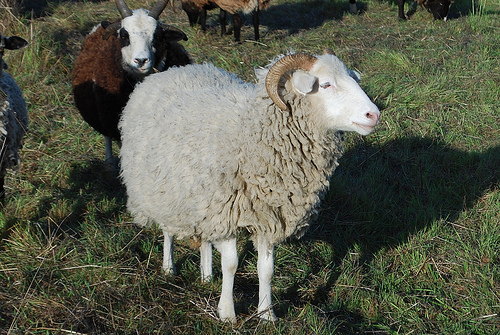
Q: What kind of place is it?
A: It is a pasture.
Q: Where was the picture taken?
A: It was taken at the pasture.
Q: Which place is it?
A: It is a pasture.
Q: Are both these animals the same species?
A: Yes, all the animals are sheep.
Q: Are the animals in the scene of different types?
A: No, all the animals are sheep.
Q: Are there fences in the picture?
A: No, there are no fences.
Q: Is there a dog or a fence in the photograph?
A: No, there are no fences or dogs.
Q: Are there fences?
A: No, there are no fences.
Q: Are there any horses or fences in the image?
A: No, there are no fences or horses.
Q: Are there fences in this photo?
A: No, there are no fences.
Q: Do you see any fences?
A: No, there are no fences.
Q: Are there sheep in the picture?
A: Yes, there is a sheep.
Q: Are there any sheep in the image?
A: Yes, there is a sheep.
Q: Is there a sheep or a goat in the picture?
A: Yes, there is a sheep.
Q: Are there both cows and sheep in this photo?
A: No, there is a sheep but no cows.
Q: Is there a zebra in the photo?
A: No, there are no zebras.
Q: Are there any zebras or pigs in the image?
A: No, there are no zebras or pigs.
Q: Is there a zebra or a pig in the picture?
A: No, there are no zebras or pigs.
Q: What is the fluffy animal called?
A: The animal is a sheep.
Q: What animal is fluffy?
A: The animal is a sheep.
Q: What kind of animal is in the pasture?
A: The animal is a sheep.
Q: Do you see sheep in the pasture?
A: Yes, there is a sheep in the pasture.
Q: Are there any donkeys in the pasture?
A: No, there is a sheep in the pasture.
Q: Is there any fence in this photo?
A: No, there are no fences.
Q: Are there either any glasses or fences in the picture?
A: No, there are no fences or glasses.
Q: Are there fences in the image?
A: No, there are no fences.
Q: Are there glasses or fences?
A: No, there are no fences or glasses.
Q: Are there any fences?
A: No, there are no fences.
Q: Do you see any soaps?
A: No, there are no soaps.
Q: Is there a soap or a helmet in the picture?
A: No, there are no soaps or helmets.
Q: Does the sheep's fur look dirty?
A: Yes, the fur is dirty.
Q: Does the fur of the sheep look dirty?
A: Yes, the fur is dirty.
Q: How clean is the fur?
A: The fur is dirty.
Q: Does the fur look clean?
A: No, the fur is dirty.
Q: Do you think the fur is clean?
A: No, the fur is dirty.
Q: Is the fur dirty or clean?
A: The fur is dirty.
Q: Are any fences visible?
A: No, there are no fences.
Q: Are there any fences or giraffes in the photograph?
A: No, there are no fences or giraffes.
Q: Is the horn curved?
A: Yes, the horn is curved.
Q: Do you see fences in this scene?
A: No, there are no fences.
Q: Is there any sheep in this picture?
A: Yes, there is a sheep.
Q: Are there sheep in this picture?
A: Yes, there is a sheep.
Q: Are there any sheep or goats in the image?
A: Yes, there is a sheep.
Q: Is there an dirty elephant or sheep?
A: Yes, there is a dirty sheep.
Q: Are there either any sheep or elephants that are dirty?
A: Yes, the sheep is dirty.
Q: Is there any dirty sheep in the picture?
A: Yes, there is a dirty sheep.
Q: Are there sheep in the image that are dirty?
A: Yes, there is a sheep that is dirty.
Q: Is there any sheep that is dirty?
A: Yes, there is a sheep that is dirty.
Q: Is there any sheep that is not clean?
A: Yes, there is a dirty sheep.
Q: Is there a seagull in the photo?
A: No, there are no seagulls.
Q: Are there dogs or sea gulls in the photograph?
A: No, there are no sea gulls or dogs.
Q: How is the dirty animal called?
A: The animal is a sheep.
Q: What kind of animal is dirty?
A: The animal is a sheep.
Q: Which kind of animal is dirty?
A: The animal is a sheep.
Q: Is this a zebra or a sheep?
A: This is a sheep.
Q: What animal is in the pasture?
A: The sheep is in the pasture.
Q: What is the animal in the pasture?
A: The animal is a sheep.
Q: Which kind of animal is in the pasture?
A: The animal is a sheep.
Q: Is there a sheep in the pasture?
A: Yes, there is a sheep in the pasture.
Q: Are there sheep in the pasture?
A: Yes, there is a sheep in the pasture.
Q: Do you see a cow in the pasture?
A: No, there is a sheep in the pasture.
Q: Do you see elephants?
A: No, there are no elephants.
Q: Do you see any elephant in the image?
A: No, there are no elephants.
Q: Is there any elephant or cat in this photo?
A: No, there are no elephants or cats.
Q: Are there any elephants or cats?
A: No, there are no elephants or cats.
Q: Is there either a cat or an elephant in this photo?
A: No, there are no elephants or cats.